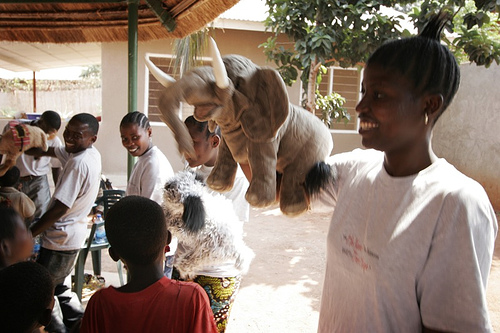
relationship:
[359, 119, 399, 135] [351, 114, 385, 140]
teeth in mouth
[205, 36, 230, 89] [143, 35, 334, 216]
horns on elephant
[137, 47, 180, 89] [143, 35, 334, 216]
tusk on elephant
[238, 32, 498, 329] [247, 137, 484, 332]
woman wearing t-shirt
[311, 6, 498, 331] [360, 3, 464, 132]
woman has hair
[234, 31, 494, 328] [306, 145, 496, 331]
person wearing shirt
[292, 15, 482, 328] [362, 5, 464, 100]
person has hair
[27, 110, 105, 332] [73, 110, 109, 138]
person has hair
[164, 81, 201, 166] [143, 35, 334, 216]
trunk on elephant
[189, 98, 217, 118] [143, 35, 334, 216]
mouth on elephant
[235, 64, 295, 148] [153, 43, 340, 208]
ear on elephant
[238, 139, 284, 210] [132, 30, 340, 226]
leg on elephant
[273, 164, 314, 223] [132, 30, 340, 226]
leg on elephant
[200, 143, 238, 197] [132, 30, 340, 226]
leg on elephant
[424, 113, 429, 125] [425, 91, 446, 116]
earring on ear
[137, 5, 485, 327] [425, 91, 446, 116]
woman has ear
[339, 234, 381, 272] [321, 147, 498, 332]
words on shirt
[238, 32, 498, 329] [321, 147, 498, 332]
woman has shirt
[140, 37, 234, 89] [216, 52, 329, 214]
tusks on elephant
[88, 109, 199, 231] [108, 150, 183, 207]
person wears gray shirt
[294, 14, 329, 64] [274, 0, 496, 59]
leaves on tree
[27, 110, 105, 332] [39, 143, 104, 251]
person wearing shirt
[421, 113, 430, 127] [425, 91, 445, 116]
earring on ear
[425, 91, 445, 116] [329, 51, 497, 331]
ear of woman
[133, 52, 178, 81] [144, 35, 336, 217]
horns of elephant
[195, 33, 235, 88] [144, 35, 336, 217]
horns of elephant